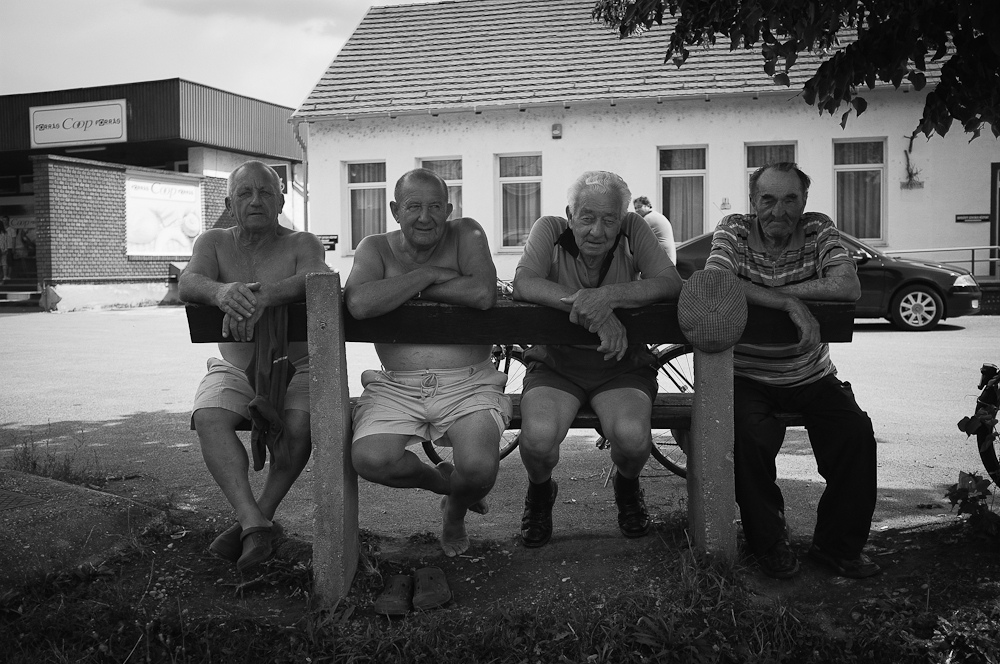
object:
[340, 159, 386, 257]
window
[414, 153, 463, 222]
window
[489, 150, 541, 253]
window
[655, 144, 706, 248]
window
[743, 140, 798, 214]
window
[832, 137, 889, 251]
window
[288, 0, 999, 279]
building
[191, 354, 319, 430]
shorts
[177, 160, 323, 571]
man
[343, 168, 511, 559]
man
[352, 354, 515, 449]
shorts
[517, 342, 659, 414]
shorts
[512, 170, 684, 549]
man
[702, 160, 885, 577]
man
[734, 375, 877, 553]
pants